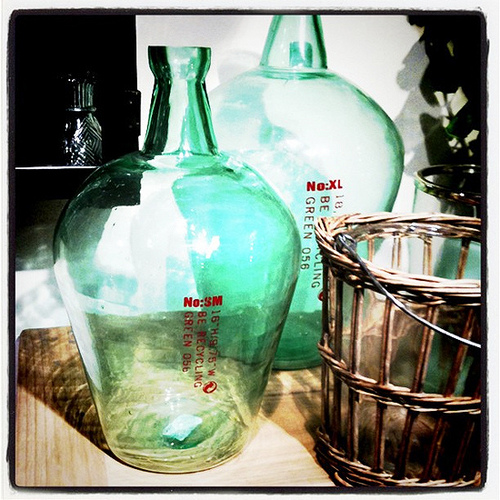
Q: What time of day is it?
A: Daytime.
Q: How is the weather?
A: Sunny.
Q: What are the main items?
A: Large vases.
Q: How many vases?
A: Two.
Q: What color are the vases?
A: Clear glass.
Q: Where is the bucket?
A: Right of the vases.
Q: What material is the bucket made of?
A: Wood.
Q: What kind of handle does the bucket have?
A: A metal handle.